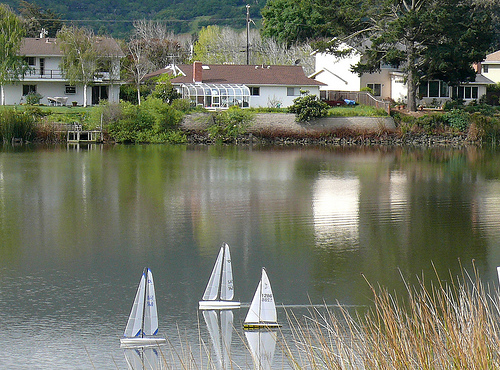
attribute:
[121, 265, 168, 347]
sailboat — toy, white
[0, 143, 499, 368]
water — calm, still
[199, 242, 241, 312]
sailboat — toy, white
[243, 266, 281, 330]
sailboat — toy, white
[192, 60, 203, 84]
chimney — brick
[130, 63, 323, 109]
house — white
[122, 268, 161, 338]
sail — white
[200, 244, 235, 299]
sail — white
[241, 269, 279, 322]
sail — white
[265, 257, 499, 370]
grass — tall, brown, high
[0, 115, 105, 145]
dock — brown, wood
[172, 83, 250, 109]
greenhouse — glass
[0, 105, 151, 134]
backyard — green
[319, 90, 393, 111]
fence — wood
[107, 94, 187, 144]
bush — green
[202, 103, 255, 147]
bush — green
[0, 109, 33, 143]
bush — green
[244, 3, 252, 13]
light — off